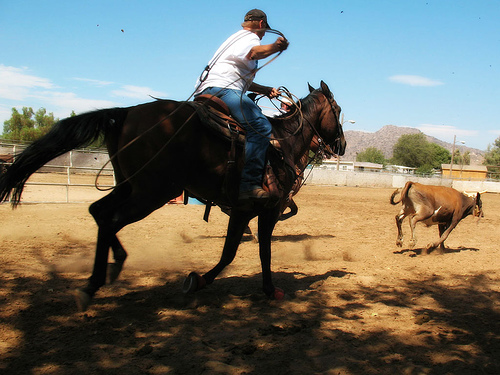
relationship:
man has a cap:
[194, 8, 286, 201] [244, 8, 272, 29]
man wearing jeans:
[194, 8, 286, 201] [196, 84, 267, 189]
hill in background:
[343, 126, 490, 162] [4, 97, 497, 211]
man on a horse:
[3, 5, 499, 370] [1, 7, 499, 374]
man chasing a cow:
[3, 5, 499, 370] [386, 165, 486, 258]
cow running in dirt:
[390, 181, 484, 256] [316, 242, 452, 285]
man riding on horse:
[194, 8, 286, 201] [2, 78, 347, 311]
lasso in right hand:
[96, 27, 306, 192] [271, 35, 290, 53]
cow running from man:
[381, 176, 478, 254] [194, 8, 286, 201]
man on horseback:
[194, 8, 286, 201] [175, 84, 280, 147]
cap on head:
[236, 7, 275, 25] [241, 2, 268, 43]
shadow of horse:
[79, 268, 354, 323] [2, 78, 347, 311]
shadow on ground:
[0, 234, 500, 375] [3, 172, 496, 369]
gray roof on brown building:
[441, 162, 488, 173] [442, 161, 487, 181]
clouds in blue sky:
[2, 67, 129, 134] [0, 0, 500, 151]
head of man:
[243, 7, 268, 36] [202, 9, 292, 198]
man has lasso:
[194, 8, 286, 201] [213, 33, 303, 123]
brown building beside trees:
[441, 164, 487, 181] [397, 133, 441, 166]